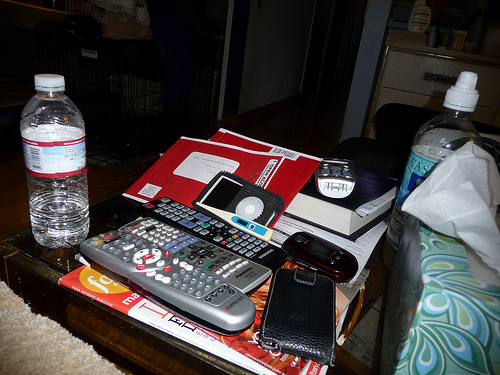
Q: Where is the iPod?
A: On the table.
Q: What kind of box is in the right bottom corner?
A: Tissue box.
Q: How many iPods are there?
A: One.